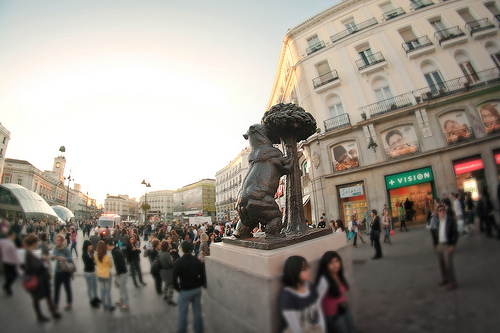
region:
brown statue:
[243, 97, 322, 236]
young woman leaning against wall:
[277, 248, 321, 326]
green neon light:
[377, 163, 435, 189]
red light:
[446, 152, 488, 182]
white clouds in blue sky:
[31, 19, 95, 64]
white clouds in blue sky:
[70, 78, 121, 118]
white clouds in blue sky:
[102, 109, 167, 164]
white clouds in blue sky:
[131, 33, 174, 95]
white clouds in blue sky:
[196, 37, 231, 98]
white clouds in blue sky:
[18, 17, 110, 90]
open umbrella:
[12, 180, 67, 221]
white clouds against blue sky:
[21, 9, 81, 66]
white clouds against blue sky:
[16, 60, 76, 112]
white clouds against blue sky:
[104, 45, 153, 114]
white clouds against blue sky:
[111, 95, 183, 165]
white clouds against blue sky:
[181, 34, 248, 92]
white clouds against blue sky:
[59, 8, 136, 83]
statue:
[249, 100, 319, 241]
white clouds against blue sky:
[88, 101, 150, 133]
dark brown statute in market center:
[233, 108, 310, 218]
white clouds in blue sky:
[11, 14, 46, 48]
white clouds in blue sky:
[16, 60, 47, 80]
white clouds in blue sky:
[76, 14, 128, 51]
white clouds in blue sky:
[67, 70, 132, 107]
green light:
[370, 165, 436, 194]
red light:
[427, 139, 484, 174]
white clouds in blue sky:
[116, 97, 179, 134]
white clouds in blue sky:
[187, 59, 228, 113]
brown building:
[303, 29, 442, 94]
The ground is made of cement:
[378, 273, 434, 316]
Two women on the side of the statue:
[273, 251, 363, 331]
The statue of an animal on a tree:
[226, 101, 326, 236]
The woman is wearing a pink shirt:
[321, 273, 352, 315]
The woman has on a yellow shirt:
[93, 253, 115, 278]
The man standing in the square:
[421, 200, 468, 292]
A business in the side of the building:
[375, 159, 437, 234]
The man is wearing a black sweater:
[170, 240, 210, 294]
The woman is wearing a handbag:
[17, 249, 49, 296]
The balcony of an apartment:
[344, 40, 394, 80]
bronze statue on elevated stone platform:
[200, 98, 345, 326]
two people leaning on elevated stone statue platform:
[265, 245, 372, 331]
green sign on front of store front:
[382, 163, 436, 189]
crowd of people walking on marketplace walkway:
[4, 178, 498, 332]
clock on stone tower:
[51, 157, 63, 172]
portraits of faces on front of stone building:
[318, 97, 497, 172]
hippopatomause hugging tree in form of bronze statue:
[230, 96, 320, 238]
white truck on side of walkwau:
[89, 207, 123, 236]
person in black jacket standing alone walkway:
[421, 198, 466, 293]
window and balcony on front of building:
[360, 75, 414, 117]